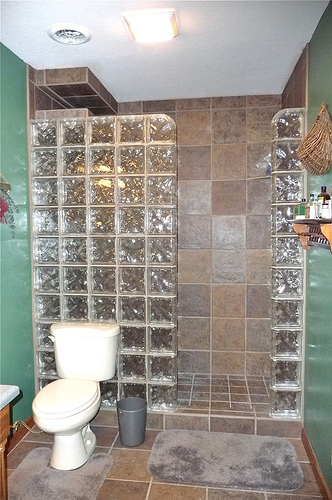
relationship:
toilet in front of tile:
[29, 320, 121, 466] [31, 114, 178, 406]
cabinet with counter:
[0, 416, 12, 495] [0, 383, 20, 406]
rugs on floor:
[18, 429, 312, 498] [22, 407, 319, 491]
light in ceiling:
[119, 7, 179, 45] [6, 4, 319, 101]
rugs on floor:
[18, 429, 312, 498] [100, 411, 304, 498]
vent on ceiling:
[46, 24, 91, 45] [3, 2, 317, 69]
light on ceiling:
[119, 7, 179, 45] [2, 1, 317, 61]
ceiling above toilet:
[3, 2, 321, 79] [32, 318, 124, 471]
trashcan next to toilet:
[117, 394, 147, 446] [32, 318, 124, 471]